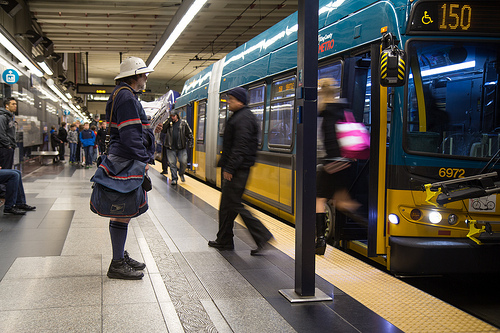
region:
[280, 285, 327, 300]
Metallic metal base holding iron beam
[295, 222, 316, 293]
Grey iron beam supporting roof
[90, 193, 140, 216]
Satchet hanging on the side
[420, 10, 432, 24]
Yellow sign for invalids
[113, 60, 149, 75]
A wide brimmed hat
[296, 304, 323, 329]
Dark color platform floor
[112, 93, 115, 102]
Strap on the shoulder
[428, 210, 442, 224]
Shining light on train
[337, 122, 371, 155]
A yellow and pink bag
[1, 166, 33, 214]
The legs of a man sitting down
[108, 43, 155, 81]
The canvas hat on the mans head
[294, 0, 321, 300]
a black pillar on the platform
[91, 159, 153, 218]
the postal bag at the mans waist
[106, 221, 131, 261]
A long blue sock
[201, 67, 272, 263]
a man walking out of the train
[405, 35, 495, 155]
the front windsheild of the bus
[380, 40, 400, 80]
The side veiw mirror of the bus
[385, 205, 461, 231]
the light on the front of the bus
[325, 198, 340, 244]
the front wheel of the bus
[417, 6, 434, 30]
a handicap sign on the bus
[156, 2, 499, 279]
The train stop to down the passengers.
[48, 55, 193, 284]
There are a lot people waiting for the train.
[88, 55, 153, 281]
The old man has a hat.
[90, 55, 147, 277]
The old man has a big, blue bag.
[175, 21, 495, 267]
The train is color blue an yellow.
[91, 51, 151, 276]
The old man waits the train.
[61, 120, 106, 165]
A group of children waits for the train.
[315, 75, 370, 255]
A woman with a big bag is down to the train.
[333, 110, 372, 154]
The woman carries a big, pink and white bag.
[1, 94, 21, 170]
A young man is waiting for the train.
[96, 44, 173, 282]
mail man waiting for train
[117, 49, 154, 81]
hard hat on man's head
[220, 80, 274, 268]
man getting off train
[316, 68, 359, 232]
blurry photo of person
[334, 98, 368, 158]
pink and white bag on person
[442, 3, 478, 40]
train number 150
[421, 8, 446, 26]
handicapped symbol on bus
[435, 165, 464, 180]
6972 bus number on bus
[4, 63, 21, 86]
rest room sign above man's head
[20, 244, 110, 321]
tile floor at bus stop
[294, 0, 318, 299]
the pole near the train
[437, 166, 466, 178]
the numbers 6972 on the front of the train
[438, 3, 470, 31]
the numbers 150 on the front of the train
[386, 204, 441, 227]
the lights on the front of the train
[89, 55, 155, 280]
the man standing on the walkway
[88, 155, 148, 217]
the large bag the man is carrying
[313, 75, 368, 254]
the person getting off the train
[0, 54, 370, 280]
the people on the walkway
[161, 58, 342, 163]
the passenger windows on the side of the train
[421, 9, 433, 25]
the handicap sign on the front of the train